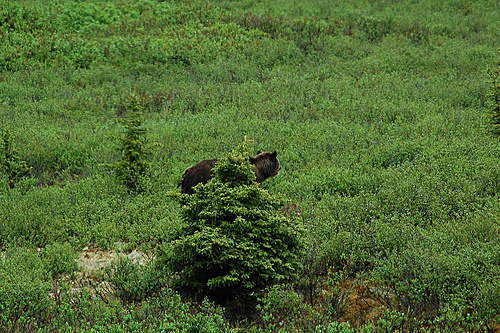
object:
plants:
[0, 0, 499, 332]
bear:
[176, 149, 282, 195]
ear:
[272, 150, 278, 157]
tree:
[160, 133, 308, 310]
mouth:
[275, 167, 281, 175]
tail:
[176, 172, 186, 189]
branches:
[302, 251, 362, 317]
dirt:
[56, 240, 157, 299]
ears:
[256, 149, 262, 155]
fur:
[175, 148, 282, 198]